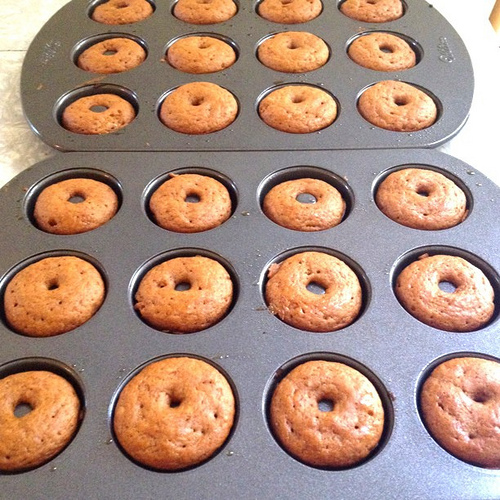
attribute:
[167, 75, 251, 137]
doughnut — baked, brown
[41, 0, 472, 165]
pan — metal, together, gray, silver, dark grey, circular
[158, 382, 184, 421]
chocolate — round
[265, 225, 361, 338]
cookie — present, baked, here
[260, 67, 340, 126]
doughnut — brown, cooked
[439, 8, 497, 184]
table — white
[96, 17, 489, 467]
goods — baked, brown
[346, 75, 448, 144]
slot — round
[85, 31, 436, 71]
items — baked